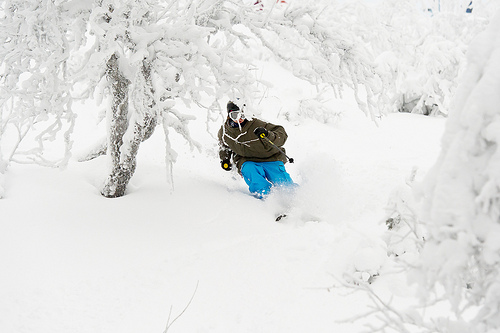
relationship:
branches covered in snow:
[147, 43, 235, 142] [180, 35, 227, 91]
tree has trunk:
[81, 15, 167, 199] [95, 58, 161, 203]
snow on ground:
[53, 184, 347, 281] [31, 200, 405, 293]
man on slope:
[221, 99, 308, 222] [180, 198, 329, 328]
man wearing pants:
[221, 99, 308, 222] [235, 159, 289, 197]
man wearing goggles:
[221, 99, 308, 222] [226, 110, 261, 123]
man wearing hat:
[221, 99, 308, 222] [221, 99, 241, 113]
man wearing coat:
[221, 99, 308, 222] [217, 119, 287, 164]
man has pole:
[221, 99, 308, 222] [256, 134, 301, 163]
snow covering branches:
[180, 35, 227, 91] [147, 43, 235, 142]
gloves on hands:
[254, 124, 266, 141] [257, 122, 275, 141]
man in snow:
[221, 99, 308, 222] [53, 184, 347, 281]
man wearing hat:
[204, 91, 290, 221] [226, 100, 246, 110]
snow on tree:
[180, 35, 227, 91] [81, 15, 167, 199]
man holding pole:
[204, 91, 290, 221] [256, 134, 301, 163]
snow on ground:
[180, 35, 227, 91] [31, 200, 405, 293]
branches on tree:
[147, 43, 235, 142] [81, 15, 167, 199]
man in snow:
[204, 91, 290, 221] [53, 184, 347, 281]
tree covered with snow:
[81, 15, 167, 199] [180, 35, 227, 91]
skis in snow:
[273, 197, 304, 228] [53, 184, 347, 281]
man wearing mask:
[204, 91, 290, 221] [220, 94, 251, 124]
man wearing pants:
[204, 91, 290, 221] [235, 159, 289, 197]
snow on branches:
[180, 35, 227, 91] [147, 43, 235, 142]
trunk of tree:
[95, 58, 161, 203] [81, 15, 167, 199]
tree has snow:
[81, 15, 167, 199] [180, 35, 227, 91]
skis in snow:
[273, 197, 304, 228] [180, 35, 227, 91]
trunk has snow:
[95, 58, 161, 203] [180, 35, 227, 91]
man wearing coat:
[221, 99, 308, 222] [196, 118, 296, 156]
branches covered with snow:
[147, 43, 235, 142] [180, 35, 227, 91]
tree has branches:
[81, 15, 167, 199] [147, 43, 235, 142]